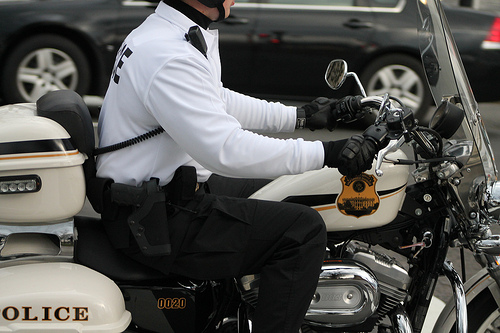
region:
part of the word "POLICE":
[1, 303, 96, 324]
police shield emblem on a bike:
[337, 170, 382, 220]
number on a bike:
[149, 290, 195, 310]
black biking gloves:
[293, 93, 377, 174]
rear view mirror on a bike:
[320, 52, 367, 99]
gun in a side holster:
[107, 172, 176, 263]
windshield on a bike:
[408, 0, 498, 187]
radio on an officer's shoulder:
[179, 25, 212, 59]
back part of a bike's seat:
[35, 84, 111, 226]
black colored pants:
[99, 183, 329, 329]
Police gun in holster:
[112, 180, 171, 259]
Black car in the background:
[0, 1, 498, 126]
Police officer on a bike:
[102, 0, 377, 329]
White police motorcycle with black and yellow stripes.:
[3, 102, 498, 330]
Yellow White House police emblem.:
[340, 172, 380, 214]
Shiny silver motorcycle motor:
[235, 255, 424, 330]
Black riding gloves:
[306, 90, 376, 172]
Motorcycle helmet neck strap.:
[203, 1, 227, 21]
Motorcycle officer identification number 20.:
[153, 291, 192, 316]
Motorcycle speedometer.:
[425, 98, 464, 138]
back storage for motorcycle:
[3, 80, 97, 219]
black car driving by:
[251, 4, 377, 103]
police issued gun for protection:
[103, 176, 176, 263]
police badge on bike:
[333, 166, 386, 218]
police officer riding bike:
[135, 8, 266, 211]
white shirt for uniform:
[93, 12, 288, 189]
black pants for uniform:
[169, 199, 301, 328]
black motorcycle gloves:
[305, 86, 378, 165]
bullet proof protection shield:
[399, 6, 496, 151]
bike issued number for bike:
[135, 286, 202, 327]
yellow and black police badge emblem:
[335, 167, 385, 225]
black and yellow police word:
[0, 290, 98, 331]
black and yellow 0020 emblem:
[153, 279, 203, 326]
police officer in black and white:
[124, 5, 339, 285]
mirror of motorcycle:
[312, 30, 383, 94]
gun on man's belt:
[94, 176, 189, 256]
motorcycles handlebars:
[335, 87, 405, 197]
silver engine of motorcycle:
[305, 222, 438, 317]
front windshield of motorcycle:
[412, 5, 498, 176]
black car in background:
[4, 10, 491, 96]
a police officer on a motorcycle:
[98, 0, 375, 332]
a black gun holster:
[110, 176, 174, 263]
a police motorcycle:
[3, 58, 495, 331]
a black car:
[1, 0, 498, 122]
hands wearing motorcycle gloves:
[290, 96, 381, 178]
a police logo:
[335, 169, 380, 218]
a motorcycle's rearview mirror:
[323, 57, 386, 96]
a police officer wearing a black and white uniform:
[94, 0, 321, 332]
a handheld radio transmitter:
[75, 24, 211, 158]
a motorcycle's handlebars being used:
[303, 92, 422, 174]